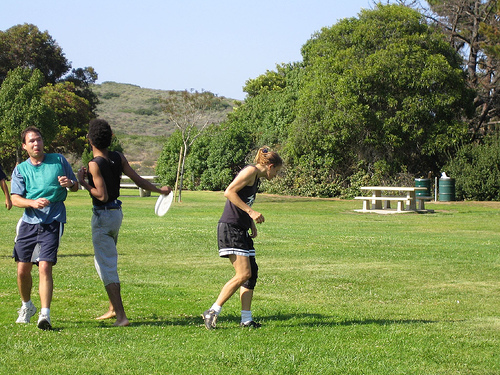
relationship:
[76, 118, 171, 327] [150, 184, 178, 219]
man with frisbee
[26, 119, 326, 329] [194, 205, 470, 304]
people playing in a field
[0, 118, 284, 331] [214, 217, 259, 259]
people in shorts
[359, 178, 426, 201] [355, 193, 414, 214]
table with bench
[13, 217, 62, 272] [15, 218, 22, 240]
shorts with stripe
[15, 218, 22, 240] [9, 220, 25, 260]
stripe on side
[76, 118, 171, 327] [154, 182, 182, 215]
man playing frisbee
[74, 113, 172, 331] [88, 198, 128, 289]
man wearing capris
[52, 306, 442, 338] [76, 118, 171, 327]
shadow of man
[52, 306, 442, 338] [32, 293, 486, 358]
shadow on ground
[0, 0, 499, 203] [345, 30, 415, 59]
green leaves on branches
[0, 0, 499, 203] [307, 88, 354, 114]
green leaves on branches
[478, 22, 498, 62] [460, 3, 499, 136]
green leaves on branches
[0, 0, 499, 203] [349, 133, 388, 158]
green leaves on branches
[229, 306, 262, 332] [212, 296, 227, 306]
socks slouched a quarter up calf